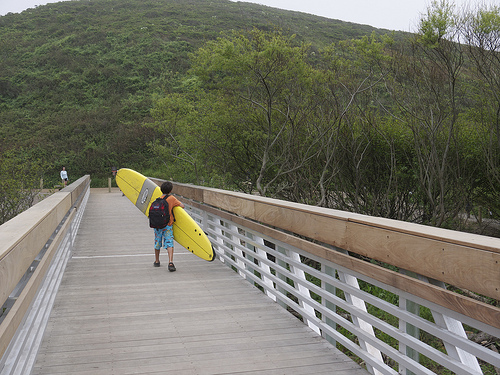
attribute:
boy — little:
[147, 182, 179, 274]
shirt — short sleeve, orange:
[152, 194, 184, 221]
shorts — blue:
[150, 225, 175, 252]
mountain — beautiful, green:
[2, 4, 497, 203]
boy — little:
[108, 161, 214, 286]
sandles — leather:
[137, 244, 185, 273]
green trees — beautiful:
[1, 7, 495, 224]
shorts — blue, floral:
[146, 219, 186, 257]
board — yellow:
[75, 144, 242, 301]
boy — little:
[140, 175, 181, 268]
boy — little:
[135, 168, 193, 287]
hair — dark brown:
[155, 174, 175, 198]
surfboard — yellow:
[106, 155, 223, 267]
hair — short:
[158, 177, 176, 199]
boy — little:
[149, 178, 184, 273]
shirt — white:
[56, 167, 71, 177]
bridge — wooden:
[0, 174, 498, 371]